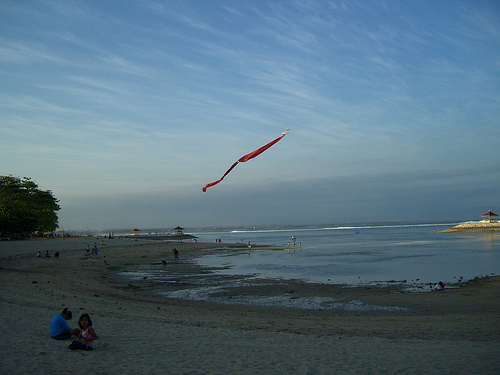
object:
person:
[50, 307, 80, 342]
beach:
[0, 233, 500, 374]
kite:
[200, 128, 291, 194]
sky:
[0, 0, 500, 233]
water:
[80, 218, 499, 314]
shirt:
[50, 313, 74, 335]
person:
[67, 312, 100, 352]